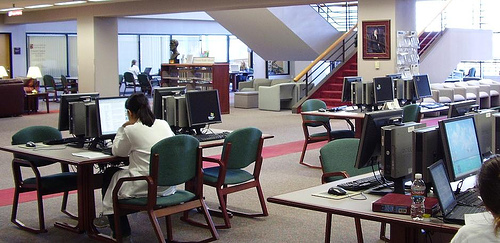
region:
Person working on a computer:
[93, 89, 182, 199]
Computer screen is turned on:
[435, 111, 487, 183]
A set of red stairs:
[295, 50, 360, 111]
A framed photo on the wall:
[359, 18, 395, 62]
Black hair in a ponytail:
[120, 89, 159, 130]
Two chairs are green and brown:
[108, 123, 273, 241]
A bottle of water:
[405, 170, 430, 222]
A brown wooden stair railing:
[290, 18, 358, 83]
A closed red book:
[369, 189, 443, 219]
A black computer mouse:
[321, 179, 349, 199]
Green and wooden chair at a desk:
[290, 89, 322, 183]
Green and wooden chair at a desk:
[205, 128, 280, 233]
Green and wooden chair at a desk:
[101, 126, 209, 242]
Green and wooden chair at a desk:
[0, 116, 76, 231]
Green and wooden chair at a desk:
[119, 69, 141, 93]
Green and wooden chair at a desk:
[308, 141, 367, 231]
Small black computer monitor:
[179, 91, 229, 129]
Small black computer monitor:
[93, 91, 132, 132]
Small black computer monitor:
[439, 111, 482, 179]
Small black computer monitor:
[353, 91, 399, 182]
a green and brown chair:
[190, 125, 273, 219]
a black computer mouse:
[325, 185, 344, 196]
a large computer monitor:
[442, 115, 487, 178]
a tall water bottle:
[409, 173, 429, 215]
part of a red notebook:
[368, 184, 436, 215]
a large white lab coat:
[100, 117, 185, 217]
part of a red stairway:
[317, 61, 356, 106]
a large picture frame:
[359, 19, 393, 64]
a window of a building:
[229, 35, 251, 70]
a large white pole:
[77, 15, 118, 96]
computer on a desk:
[85, 92, 147, 157]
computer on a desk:
[60, 91, 101, 138]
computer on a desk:
[183, 85, 235, 136]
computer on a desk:
[149, 73, 193, 127]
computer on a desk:
[350, 103, 405, 181]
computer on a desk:
[415, 113, 490, 215]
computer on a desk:
[409, 169, 483, 229]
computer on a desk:
[363, 68, 408, 113]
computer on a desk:
[407, 71, 449, 109]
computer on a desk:
[322, 73, 370, 115]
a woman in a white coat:
[94, 95, 174, 239]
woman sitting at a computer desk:
[91, 88, 175, 241]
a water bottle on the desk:
[408, 169, 426, 219]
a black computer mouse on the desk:
[322, 182, 347, 198]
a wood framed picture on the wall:
[358, 17, 390, 64]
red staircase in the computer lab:
[306, 54, 363, 112]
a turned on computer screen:
[441, 116, 483, 181]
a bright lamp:
[26, 65, 46, 80]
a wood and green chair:
[202, 128, 278, 230]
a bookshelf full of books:
[155, 62, 242, 109]